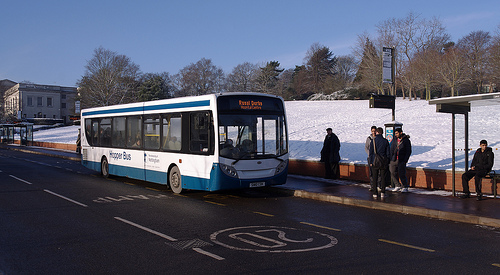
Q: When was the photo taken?
A: During the day.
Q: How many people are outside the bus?
A: Five.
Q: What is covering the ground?
A: Snow.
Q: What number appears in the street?
A: 20.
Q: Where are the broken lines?
A: In the street.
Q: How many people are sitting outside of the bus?
A: One.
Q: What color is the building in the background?
A: Grey.